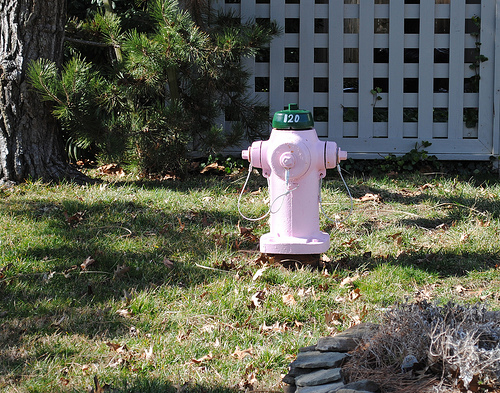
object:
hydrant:
[236, 99, 354, 267]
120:
[281, 110, 303, 126]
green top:
[269, 101, 319, 132]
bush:
[24, 1, 285, 185]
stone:
[311, 315, 378, 352]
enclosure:
[277, 302, 497, 393]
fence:
[202, 0, 499, 169]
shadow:
[362, 166, 494, 230]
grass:
[4, 165, 498, 383]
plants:
[231, 280, 278, 313]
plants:
[458, 11, 492, 70]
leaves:
[111, 300, 132, 320]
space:
[371, 46, 388, 67]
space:
[312, 17, 329, 33]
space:
[432, 77, 450, 90]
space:
[402, 17, 422, 32]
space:
[341, 105, 358, 123]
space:
[403, 108, 419, 121]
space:
[284, 74, 299, 92]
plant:
[353, 290, 500, 392]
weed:
[463, 109, 481, 128]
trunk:
[4, 2, 79, 180]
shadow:
[8, 184, 224, 344]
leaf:
[77, 251, 98, 275]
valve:
[267, 135, 313, 187]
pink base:
[252, 233, 336, 258]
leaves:
[358, 189, 383, 204]